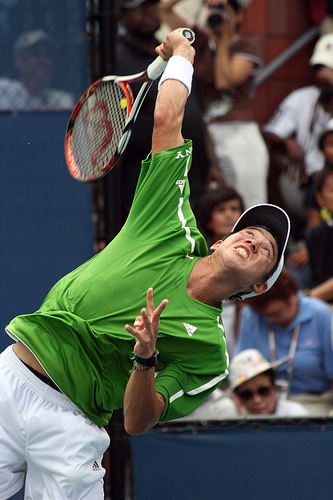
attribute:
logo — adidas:
[183, 320, 197, 337]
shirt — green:
[4, 139, 230, 430]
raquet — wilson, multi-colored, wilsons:
[64, 28, 194, 183]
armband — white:
[157, 54, 193, 95]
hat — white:
[229, 199, 289, 302]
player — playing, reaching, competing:
[2, 26, 289, 499]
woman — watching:
[206, 348, 307, 420]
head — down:
[249, 272, 300, 326]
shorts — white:
[0, 345, 112, 500]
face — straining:
[218, 226, 278, 285]